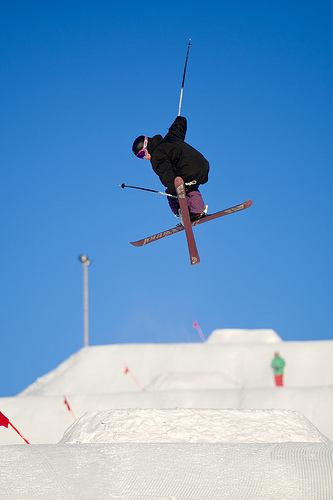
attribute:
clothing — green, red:
[262, 343, 308, 380]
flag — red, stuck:
[0, 394, 33, 455]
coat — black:
[148, 132, 250, 211]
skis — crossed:
[96, 158, 281, 282]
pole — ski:
[159, 13, 235, 136]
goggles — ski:
[118, 134, 159, 167]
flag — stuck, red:
[3, 399, 48, 463]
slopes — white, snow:
[139, 363, 278, 498]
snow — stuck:
[37, 441, 104, 479]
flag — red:
[0, 396, 42, 463]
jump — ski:
[203, 311, 308, 364]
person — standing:
[259, 341, 295, 407]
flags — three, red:
[5, 355, 160, 446]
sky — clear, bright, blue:
[35, 45, 100, 126]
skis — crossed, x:
[124, 176, 269, 303]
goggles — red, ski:
[106, 130, 162, 163]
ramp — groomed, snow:
[109, 381, 299, 497]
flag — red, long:
[44, 379, 91, 423]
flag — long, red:
[49, 394, 98, 435]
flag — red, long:
[121, 362, 143, 392]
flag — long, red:
[60, 394, 78, 424]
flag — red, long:
[57, 392, 78, 423]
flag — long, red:
[120, 362, 146, 392]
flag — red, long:
[62, 392, 75, 417]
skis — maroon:
[128, 175, 253, 266]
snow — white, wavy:
[1, 326, 322, 498]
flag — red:
[0, 409, 30, 444]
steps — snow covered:
[2, 406, 322, 497]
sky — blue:
[2, 1, 322, 395]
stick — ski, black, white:
[119, 182, 178, 200]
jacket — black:
[146, 115, 211, 198]